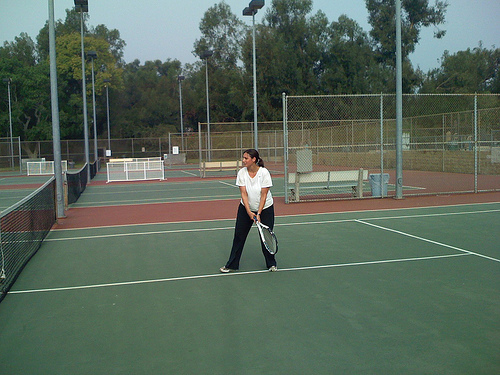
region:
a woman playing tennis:
[221, 105, 282, 319]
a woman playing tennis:
[224, 171, 299, 373]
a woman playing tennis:
[228, 83, 356, 362]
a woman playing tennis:
[179, 106, 313, 369]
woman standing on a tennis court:
[205, 128, 292, 310]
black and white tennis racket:
[246, 201, 287, 271]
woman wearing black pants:
[224, 129, 304, 309]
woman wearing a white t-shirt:
[210, 132, 292, 304]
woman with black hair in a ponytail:
[227, 138, 285, 187]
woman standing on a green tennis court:
[83, 127, 383, 324]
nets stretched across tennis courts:
[13, 140, 129, 305]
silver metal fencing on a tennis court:
[168, 92, 457, 186]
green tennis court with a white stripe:
[64, 270, 199, 354]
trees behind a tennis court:
[180, 12, 425, 139]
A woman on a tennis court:
[135, 100, 344, 291]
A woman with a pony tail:
[234, 136, 269, 176]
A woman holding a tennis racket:
[216, 134, 301, 294]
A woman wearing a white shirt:
[205, 131, 309, 282]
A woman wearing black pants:
[202, 138, 306, 288]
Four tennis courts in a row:
[13, 103, 495, 347]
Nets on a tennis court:
[46, 153, 117, 223]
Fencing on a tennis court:
[253, 62, 485, 254]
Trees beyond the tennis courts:
[5, 16, 474, 182]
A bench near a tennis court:
[191, 153, 241, 175]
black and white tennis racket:
[253, 217, 284, 262]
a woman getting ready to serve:
[173, 138, 303, 297]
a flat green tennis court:
[339, 308, 445, 353]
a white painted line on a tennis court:
[78, 269, 124, 310]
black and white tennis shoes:
[198, 263, 284, 283]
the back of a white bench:
[283, 161, 369, 198]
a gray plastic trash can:
[363, 169, 399, 208]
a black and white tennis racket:
[248, 208, 283, 263]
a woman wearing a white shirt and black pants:
[210, 156, 283, 278]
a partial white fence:
[105, 160, 175, 179]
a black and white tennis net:
[6, 183, 65, 270]